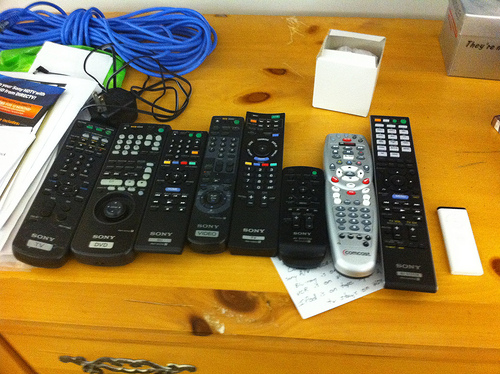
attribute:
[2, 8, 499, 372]
table — brown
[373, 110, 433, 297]
remote — collected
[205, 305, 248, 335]
paint — white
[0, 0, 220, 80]
bound wire — blue, long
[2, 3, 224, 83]
cord — blue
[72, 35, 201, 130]
plug — black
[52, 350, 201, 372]
handle — golden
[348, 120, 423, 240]
remote control — several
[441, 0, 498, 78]
box — silver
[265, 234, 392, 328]
paper — white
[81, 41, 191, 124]
cord — power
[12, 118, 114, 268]
controller — black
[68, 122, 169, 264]
controller — sony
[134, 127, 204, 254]
controller — sony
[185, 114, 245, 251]
controller — black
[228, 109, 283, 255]
controller — black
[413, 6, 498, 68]
side box — silver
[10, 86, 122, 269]
control — different sized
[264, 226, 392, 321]
card — index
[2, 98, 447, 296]
remotes controls — different, eight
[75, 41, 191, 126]
charger — black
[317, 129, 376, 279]
comcast remote — silver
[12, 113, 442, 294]
remotes — various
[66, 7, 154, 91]
wire — blue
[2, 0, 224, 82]
blue wires — bunch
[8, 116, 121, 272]
remote control — white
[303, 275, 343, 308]
note — white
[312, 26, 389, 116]
box — open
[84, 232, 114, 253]
sony — white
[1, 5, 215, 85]
wire — blue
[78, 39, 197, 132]
charger — black